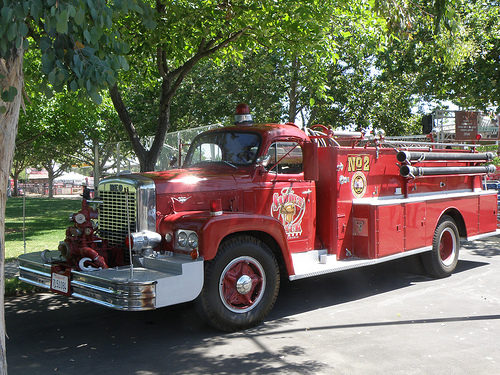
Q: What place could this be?
A: It is a road.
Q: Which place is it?
A: It is a road.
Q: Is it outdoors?
A: Yes, it is outdoors.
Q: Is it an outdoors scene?
A: Yes, it is outdoors.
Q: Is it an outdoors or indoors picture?
A: It is outdoors.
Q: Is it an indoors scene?
A: No, it is outdoors.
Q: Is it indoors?
A: No, it is outdoors.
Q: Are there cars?
A: No, there are no cars.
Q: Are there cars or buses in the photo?
A: No, there are no cars or buses.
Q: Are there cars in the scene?
A: No, there are no cars.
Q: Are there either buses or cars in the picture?
A: No, there are no cars or buses.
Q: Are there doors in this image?
A: Yes, there is a door.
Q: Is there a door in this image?
A: Yes, there is a door.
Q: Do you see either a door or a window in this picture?
A: Yes, there is a door.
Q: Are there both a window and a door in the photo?
A: Yes, there are both a door and a window.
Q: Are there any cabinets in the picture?
A: No, there are no cabinets.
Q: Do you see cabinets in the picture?
A: No, there are no cabinets.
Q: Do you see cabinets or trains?
A: No, there are no cabinets or trains.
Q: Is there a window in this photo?
A: Yes, there is a window.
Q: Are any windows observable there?
A: Yes, there is a window.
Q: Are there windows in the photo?
A: Yes, there is a window.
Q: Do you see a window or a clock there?
A: Yes, there is a window.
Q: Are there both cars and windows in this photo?
A: No, there is a window but no cars.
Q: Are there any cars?
A: No, there are no cars.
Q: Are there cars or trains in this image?
A: No, there are no cars or trains.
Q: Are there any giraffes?
A: No, there are no giraffes.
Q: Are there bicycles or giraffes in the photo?
A: No, there are no giraffes or bicycles.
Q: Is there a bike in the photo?
A: No, there are no bikes.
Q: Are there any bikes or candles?
A: No, there are no bikes or candles.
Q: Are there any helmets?
A: No, there are no helmets.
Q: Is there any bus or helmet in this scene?
A: No, there are no helmets or buses.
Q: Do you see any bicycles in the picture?
A: No, there are no bicycles.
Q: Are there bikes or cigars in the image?
A: No, there are no bikes or cigars.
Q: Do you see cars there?
A: No, there are no cars.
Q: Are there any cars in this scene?
A: No, there are no cars.